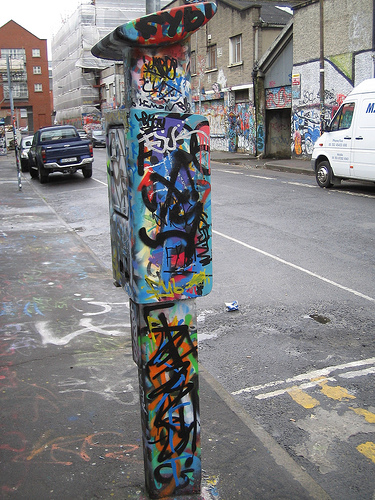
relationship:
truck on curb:
[27, 125, 94, 186] [16, 164, 323, 498]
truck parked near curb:
[27, 125, 94, 186] [0, 151, 338, 498]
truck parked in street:
[27, 125, 94, 186] [32, 144, 370, 494]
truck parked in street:
[18, 129, 94, 186] [32, 144, 370, 494]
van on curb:
[310, 70, 374, 187] [259, 157, 313, 180]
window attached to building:
[30, 45, 42, 60] [1, 17, 50, 136]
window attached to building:
[222, 27, 248, 72] [186, 21, 296, 159]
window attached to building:
[204, 40, 218, 74] [193, 23, 272, 165]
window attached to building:
[183, 50, 202, 82] [183, 17, 281, 162]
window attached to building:
[25, 45, 39, 59] [3, 21, 55, 137]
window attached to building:
[29, 58, 45, 77] [3, 21, 51, 129]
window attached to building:
[29, 83, 46, 96] [1, 15, 55, 130]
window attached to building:
[3, 83, 31, 104] [3, 21, 55, 137]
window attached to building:
[3, 83, 24, 103] [3, 17, 58, 124]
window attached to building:
[200, 40, 218, 74] [186, 21, 296, 159]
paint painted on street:
[276, 363, 374, 442] [73, 162, 373, 485]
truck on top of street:
[27, 125, 94, 186] [32, 144, 370, 494]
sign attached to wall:
[285, 68, 301, 102] [285, 19, 369, 178]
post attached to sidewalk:
[3, 55, 29, 192] [8, 160, 298, 499]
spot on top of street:
[297, 299, 334, 329] [103, 140, 371, 493]